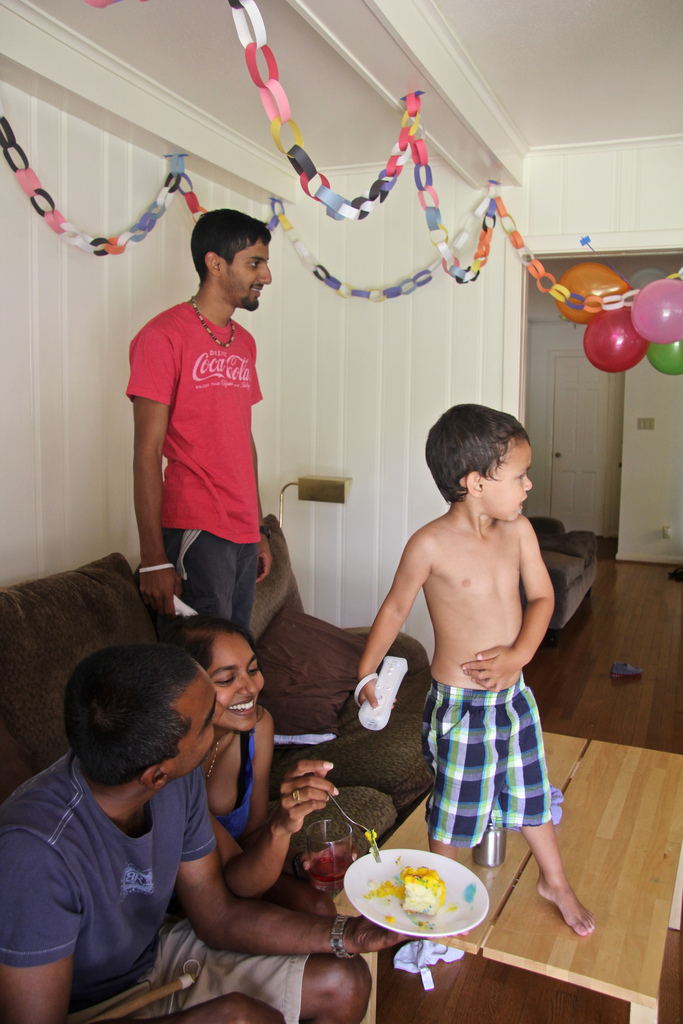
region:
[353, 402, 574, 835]
A boy with no shirt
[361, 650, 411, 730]
A remote control in a boy's hand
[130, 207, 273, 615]
Man standing on a couch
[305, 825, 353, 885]
A glass in a woman's hand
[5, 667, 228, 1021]
A man in a blue shirt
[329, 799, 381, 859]
A fork in a woman's hand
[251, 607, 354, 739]
A pillow on a couch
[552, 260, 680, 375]
Balloon on the ceiling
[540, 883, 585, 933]
foot of the boy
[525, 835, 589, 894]
leg of the person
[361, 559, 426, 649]
arm of the person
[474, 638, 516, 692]
hand of the person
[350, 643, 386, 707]
hand of the person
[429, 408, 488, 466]
hair of the perosn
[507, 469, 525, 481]
eye of the person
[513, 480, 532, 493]
nose of the person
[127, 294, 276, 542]
red and white shirt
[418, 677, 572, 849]
checkered shorts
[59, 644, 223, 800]
head is turned to the side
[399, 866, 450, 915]
hunk of meat on the plate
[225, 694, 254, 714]
big smile on the face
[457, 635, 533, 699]
hand is on the belly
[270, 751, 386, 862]
hand is holding a fork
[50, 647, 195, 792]
short black hair on the head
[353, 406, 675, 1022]
little boy is standing on the table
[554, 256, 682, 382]
a group of balloons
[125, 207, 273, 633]
Man wearing a red t-shirt.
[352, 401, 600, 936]
Boy wearing blue white and green checkered shorts.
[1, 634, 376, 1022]
Man wearing a blue t-shirt.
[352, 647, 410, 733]
Right hand holding a white Wii remote.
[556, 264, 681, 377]
Five blown up balloons.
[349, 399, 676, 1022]
Boy standing on top of a wooden table.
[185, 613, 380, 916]
Woman holding a silver fork.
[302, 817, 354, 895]
Red liquid inside a glass.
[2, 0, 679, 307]
Paper multi-colored decorations hanging from ceiling.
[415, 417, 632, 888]
a person standing niside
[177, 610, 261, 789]
a woman on the couch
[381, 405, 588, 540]
head of the kid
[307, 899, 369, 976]
watch on the wrist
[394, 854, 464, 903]
yellow frosting on food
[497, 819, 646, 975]
foot of the kid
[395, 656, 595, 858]
shorts on the kid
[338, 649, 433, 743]
white remote on boy's hand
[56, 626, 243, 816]
head of the man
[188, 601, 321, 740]
head of the lady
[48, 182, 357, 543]
man in a red shirt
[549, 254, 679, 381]
Multi-colored balloons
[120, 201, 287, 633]
Young man with red Coca-cola shirt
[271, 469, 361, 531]
Gold reading lamp next to couch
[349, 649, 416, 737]
TV game console controller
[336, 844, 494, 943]
White plate with birthday cake on it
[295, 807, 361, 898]
Drinking glass with red liquid